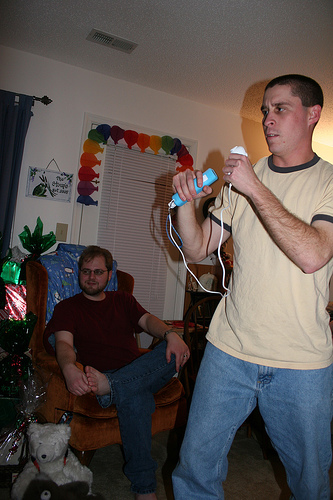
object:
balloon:
[78, 166, 99, 182]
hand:
[166, 333, 191, 373]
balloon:
[176, 154, 193, 167]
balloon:
[137, 133, 151, 153]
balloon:
[110, 125, 125, 144]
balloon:
[77, 180, 98, 195]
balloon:
[83, 139, 104, 155]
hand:
[172, 168, 212, 202]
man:
[55, 244, 191, 500]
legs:
[257, 366, 331, 500]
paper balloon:
[96, 124, 111, 145]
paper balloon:
[87, 129, 106, 145]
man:
[170, 74, 333, 500]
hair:
[265, 74, 324, 127]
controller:
[228, 146, 249, 186]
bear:
[11, 422, 93, 499]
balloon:
[80, 152, 101, 168]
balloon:
[76, 195, 97, 207]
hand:
[222, 154, 254, 197]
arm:
[177, 200, 232, 263]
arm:
[251, 177, 332, 274]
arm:
[128, 293, 175, 339]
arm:
[54, 297, 76, 368]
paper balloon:
[176, 164, 194, 172]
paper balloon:
[161, 135, 175, 155]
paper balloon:
[149, 135, 161, 155]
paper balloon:
[177, 144, 189, 158]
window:
[97, 145, 180, 348]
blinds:
[96, 144, 176, 320]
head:
[260, 74, 324, 156]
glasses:
[80, 268, 108, 275]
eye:
[262, 111, 268, 117]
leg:
[171, 340, 256, 500]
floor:
[95, 458, 120, 487]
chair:
[26, 243, 188, 466]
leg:
[115, 341, 178, 394]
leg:
[116, 390, 156, 494]